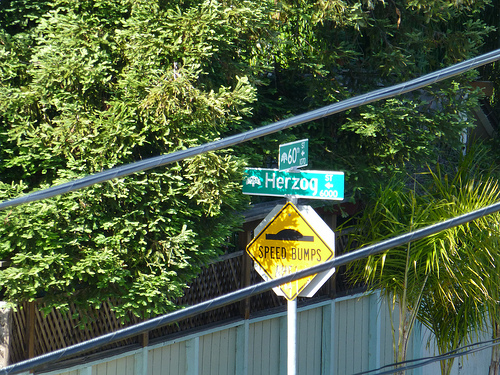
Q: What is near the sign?
A: A palm tree.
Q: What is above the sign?
A: A large area of green leaves.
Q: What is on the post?
A: A yellow sign.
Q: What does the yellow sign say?
A: SPEED BUMPS.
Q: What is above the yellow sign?
A: Street signs.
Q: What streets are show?
A: Herzog and 60th.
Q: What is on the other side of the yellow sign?
A: Stop sign.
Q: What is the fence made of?
A: Wood.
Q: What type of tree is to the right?
A: Palm.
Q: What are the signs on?
A: Poles.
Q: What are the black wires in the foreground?
A: Power lines.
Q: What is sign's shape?
A: Square.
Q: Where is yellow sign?
A: On pole.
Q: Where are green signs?
A: On pole.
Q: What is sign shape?
A: Diamond.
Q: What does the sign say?
A: Speed bumps ahead.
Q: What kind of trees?
A: Palm.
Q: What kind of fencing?
A: Wood.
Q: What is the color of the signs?
A: Yellow and green.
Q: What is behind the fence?
A: Trees.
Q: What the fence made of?
A: Wood.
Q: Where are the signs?
A: Outside the fence.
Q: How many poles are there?
A: One.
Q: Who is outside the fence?
A: No one.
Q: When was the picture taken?
A: Daytime.